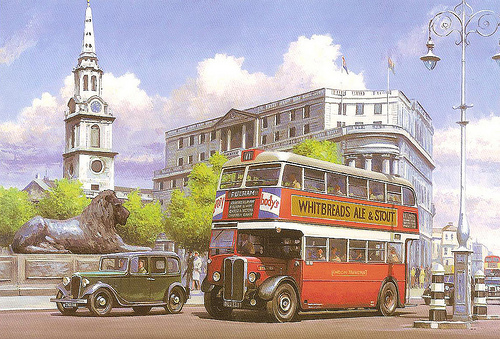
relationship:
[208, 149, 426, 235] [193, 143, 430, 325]
upper level of bus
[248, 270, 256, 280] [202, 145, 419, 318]
headlight of bus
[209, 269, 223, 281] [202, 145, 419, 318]
headlight of bus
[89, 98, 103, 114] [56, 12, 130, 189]
clock on tower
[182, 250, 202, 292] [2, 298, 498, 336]
couple walking down street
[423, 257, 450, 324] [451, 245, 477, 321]
pylons by base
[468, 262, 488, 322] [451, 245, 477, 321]
pylons by base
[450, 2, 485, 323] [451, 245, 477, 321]
post on base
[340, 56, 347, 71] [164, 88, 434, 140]
flag on balcony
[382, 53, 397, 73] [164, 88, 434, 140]
flag on balcony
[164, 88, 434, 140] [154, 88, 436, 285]
balcony on building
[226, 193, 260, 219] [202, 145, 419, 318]
placard on bus